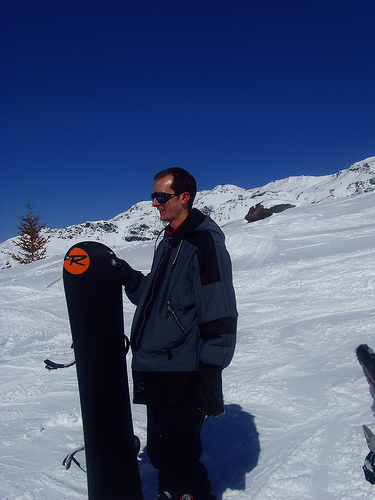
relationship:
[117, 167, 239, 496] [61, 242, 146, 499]
man has board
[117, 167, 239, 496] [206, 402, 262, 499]
man casts a shadow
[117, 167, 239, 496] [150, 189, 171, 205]
man has sunglasses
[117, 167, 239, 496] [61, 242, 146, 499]
man holding board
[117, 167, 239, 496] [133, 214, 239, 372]
man has coat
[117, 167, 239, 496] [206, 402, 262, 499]
man casts shadow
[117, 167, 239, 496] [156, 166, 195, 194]
man has hair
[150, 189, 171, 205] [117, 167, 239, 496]
sunglasses on man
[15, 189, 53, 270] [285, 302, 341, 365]
tree in snow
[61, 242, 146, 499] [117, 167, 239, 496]
board held by man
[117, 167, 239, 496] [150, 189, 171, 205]
man wearing sunglasses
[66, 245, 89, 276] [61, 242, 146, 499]
logo on board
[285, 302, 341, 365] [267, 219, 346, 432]
snow covering ground